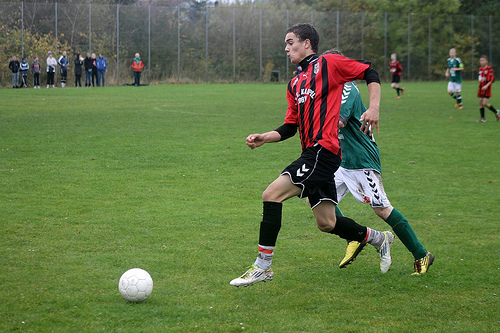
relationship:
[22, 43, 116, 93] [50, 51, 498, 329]
people watching game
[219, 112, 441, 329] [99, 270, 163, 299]
running for ball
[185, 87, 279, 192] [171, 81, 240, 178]
part of field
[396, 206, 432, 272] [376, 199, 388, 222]
sock by knee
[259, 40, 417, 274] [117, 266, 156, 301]
guys playing ball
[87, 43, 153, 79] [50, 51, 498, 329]
fans watching game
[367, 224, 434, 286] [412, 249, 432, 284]
cleats on foot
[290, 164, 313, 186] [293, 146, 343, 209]
white arrows on shorts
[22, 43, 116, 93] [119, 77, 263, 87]
people on sidelines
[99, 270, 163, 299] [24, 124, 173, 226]
ball on top of grass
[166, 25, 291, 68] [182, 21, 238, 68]
row of trees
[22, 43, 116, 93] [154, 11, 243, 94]
people by fence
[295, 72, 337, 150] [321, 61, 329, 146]
jersey has stripes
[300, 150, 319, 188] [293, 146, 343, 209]
piping on shorts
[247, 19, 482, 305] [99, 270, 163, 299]
players going for ball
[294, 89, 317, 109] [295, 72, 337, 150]
lettering on jersey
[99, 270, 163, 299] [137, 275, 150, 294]
ball has hexagon  shapes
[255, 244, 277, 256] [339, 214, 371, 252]
band on sock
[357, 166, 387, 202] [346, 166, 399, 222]
arrows on shorts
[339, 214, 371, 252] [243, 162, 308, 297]
sock on leg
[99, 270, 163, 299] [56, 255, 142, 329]
ball on ground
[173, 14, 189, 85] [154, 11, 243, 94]
poles of fence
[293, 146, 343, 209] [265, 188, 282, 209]
shorts go to knee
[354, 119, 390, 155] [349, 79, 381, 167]
stripe on shirt